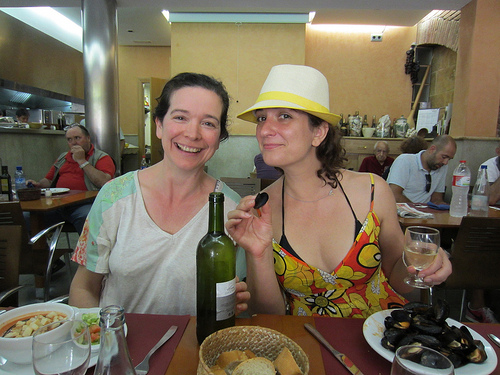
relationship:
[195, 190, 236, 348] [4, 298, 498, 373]
bottle table on table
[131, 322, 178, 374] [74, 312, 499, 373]
silver fork on table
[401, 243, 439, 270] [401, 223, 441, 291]
wine in glass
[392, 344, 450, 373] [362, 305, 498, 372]
clear glass near white plate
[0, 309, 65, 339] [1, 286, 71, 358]
soup in bowl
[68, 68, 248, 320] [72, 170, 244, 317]
woman wearing shirt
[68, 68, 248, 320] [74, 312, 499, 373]
woman sitting at table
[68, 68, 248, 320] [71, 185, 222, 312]
woman wearing shirt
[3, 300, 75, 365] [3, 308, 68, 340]
bowl in soup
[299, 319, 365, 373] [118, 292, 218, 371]
knife on table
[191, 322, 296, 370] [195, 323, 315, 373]
bread on basket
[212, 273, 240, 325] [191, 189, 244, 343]
label on bottle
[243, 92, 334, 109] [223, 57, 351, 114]
stripe on hat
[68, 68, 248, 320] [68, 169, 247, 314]
woman wearing top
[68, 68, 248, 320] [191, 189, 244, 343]
woman touching bottle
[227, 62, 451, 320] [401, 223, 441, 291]
woman holding glass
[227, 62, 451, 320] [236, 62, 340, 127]
woman wearing hat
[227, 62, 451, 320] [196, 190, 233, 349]
woman touching bottle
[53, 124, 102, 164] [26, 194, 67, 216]
man sitting at table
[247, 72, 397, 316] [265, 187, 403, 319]
woman wearing dress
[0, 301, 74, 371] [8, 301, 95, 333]
bowl of soup